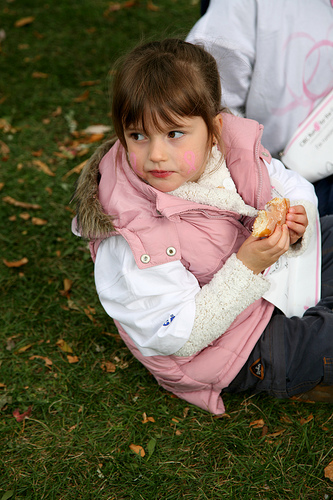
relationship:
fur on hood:
[71, 134, 115, 235] [69, 136, 185, 240]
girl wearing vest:
[65, 36, 332, 417] [70, 112, 278, 421]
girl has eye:
[65, 36, 332, 417] [167, 130, 188, 139]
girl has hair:
[65, 36, 332, 417] [108, 35, 224, 153]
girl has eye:
[65, 36, 332, 417] [128, 130, 149, 142]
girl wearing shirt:
[65, 36, 332, 417] [93, 143, 320, 358]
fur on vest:
[71, 134, 115, 235] [70, 112, 278, 421]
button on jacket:
[165, 246, 177, 258] [68, 109, 277, 417]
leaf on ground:
[128, 443, 147, 459] [1, 1, 333, 500]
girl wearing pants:
[65, 36, 332, 417] [221, 214, 332, 399]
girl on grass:
[65, 36, 332, 417] [2, 2, 332, 499]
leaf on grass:
[2, 194, 42, 213] [2, 2, 332, 499]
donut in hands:
[251, 197, 290, 239] [236, 205, 307, 274]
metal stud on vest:
[166, 245, 177, 258] [70, 112, 278, 421]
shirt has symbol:
[184, 1, 332, 156] [301, 36, 333, 131]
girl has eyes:
[65, 36, 332, 417] [126, 128, 190, 143]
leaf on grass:
[99, 359, 117, 375] [2, 2, 332, 499]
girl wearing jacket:
[65, 36, 332, 417] [68, 109, 277, 417]